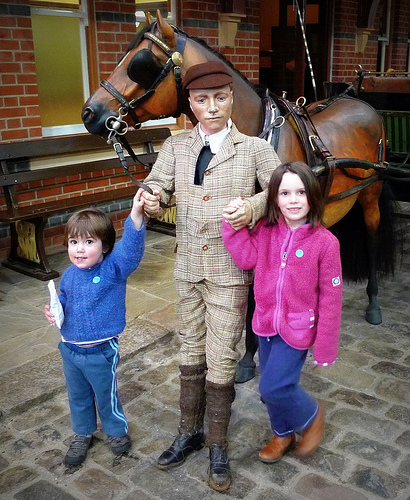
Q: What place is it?
A: It is a street.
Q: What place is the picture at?
A: It is at the street.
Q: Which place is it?
A: It is a street.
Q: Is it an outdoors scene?
A: Yes, it is outdoors.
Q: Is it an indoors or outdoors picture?
A: It is outdoors.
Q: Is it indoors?
A: No, it is outdoors.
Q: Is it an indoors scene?
A: No, it is outdoors.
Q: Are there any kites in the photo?
A: No, there are no kites.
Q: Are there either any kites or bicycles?
A: No, there are no kites or bicycles.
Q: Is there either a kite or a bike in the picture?
A: No, there are no kites or bikes.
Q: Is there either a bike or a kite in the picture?
A: No, there are no kites or bikes.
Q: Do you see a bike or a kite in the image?
A: No, there are no kites or bikes.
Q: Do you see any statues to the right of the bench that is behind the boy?
A: Yes, there is a statue to the right of the bench.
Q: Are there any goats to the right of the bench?
A: No, there is a statue to the right of the bench.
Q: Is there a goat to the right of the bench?
A: No, there is a statue to the right of the bench.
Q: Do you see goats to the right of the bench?
A: No, there is a statue to the right of the bench.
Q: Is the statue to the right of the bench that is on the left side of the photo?
A: Yes, the statue is to the right of the bench.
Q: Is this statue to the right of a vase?
A: No, the statue is to the right of the bench.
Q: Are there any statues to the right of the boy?
A: Yes, there is a statue to the right of the boy.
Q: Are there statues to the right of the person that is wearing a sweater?
A: Yes, there is a statue to the right of the boy.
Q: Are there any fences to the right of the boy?
A: No, there is a statue to the right of the boy.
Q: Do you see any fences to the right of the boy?
A: No, there is a statue to the right of the boy.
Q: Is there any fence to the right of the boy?
A: No, there is a statue to the right of the boy.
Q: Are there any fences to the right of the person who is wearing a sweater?
A: No, there is a statue to the right of the boy.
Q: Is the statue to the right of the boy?
A: Yes, the statue is to the right of the boy.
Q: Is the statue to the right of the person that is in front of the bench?
A: Yes, the statue is to the right of the boy.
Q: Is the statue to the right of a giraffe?
A: No, the statue is to the right of the boy.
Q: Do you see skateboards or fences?
A: No, there are no fences or skateboards.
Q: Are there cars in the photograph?
A: No, there are no cars.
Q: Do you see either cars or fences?
A: No, there are no cars or fences.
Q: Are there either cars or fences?
A: No, there are no cars or fences.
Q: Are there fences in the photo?
A: No, there are no fences.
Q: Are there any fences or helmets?
A: No, there are no fences or helmets.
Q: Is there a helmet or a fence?
A: No, there are no fences or helmets.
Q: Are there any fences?
A: No, there are no fences.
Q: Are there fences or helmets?
A: No, there are no fences or helmets.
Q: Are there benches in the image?
A: Yes, there is a bench.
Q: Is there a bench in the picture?
A: Yes, there is a bench.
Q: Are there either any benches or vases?
A: Yes, there is a bench.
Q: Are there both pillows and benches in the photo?
A: No, there is a bench but no pillows.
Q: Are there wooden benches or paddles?
A: Yes, there is a wood bench.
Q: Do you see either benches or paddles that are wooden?
A: Yes, the bench is wooden.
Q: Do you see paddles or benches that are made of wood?
A: Yes, the bench is made of wood.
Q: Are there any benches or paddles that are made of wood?
A: Yes, the bench is made of wood.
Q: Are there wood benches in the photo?
A: Yes, there is a wood bench.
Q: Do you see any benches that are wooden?
A: Yes, there is a wood bench.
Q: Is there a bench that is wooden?
A: Yes, there is a bench that is wooden.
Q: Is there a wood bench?
A: Yes, there is a bench that is made of wood.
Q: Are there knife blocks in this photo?
A: No, there are no knife blocks.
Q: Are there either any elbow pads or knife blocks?
A: No, there are no knife blocks or elbow pads.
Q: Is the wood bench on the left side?
A: Yes, the bench is on the left of the image.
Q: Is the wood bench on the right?
A: No, the bench is on the left of the image.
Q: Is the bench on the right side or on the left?
A: The bench is on the left of the image.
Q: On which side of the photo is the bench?
A: The bench is on the left of the image.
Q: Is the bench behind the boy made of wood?
A: Yes, the bench is made of wood.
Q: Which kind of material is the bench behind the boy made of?
A: The bench is made of wood.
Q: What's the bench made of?
A: The bench is made of wood.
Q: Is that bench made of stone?
A: No, the bench is made of wood.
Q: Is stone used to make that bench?
A: No, the bench is made of wood.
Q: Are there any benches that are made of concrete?
A: No, there is a bench but it is made of wood.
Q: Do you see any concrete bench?
A: No, there is a bench but it is made of wood.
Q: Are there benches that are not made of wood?
A: No, there is a bench but it is made of wood.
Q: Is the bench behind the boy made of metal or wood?
A: The bench is made of wood.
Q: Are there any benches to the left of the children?
A: Yes, there is a bench to the left of the children.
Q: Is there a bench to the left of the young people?
A: Yes, there is a bench to the left of the children.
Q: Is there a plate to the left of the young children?
A: No, there is a bench to the left of the children.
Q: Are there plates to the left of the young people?
A: No, there is a bench to the left of the children.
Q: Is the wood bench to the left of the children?
A: Yes, the bench is to the left of the children.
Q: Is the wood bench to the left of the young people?
A: Yes, the bench is to the left of the children.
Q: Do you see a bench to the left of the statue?
A: Yes, there is a bench to the left of the statue.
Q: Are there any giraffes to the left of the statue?
A: No, there is a bench to the left of the statue.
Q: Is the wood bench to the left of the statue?
A: Yes, the bench is to the left of the statue.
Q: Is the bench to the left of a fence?
A: No, the bench is to the left of the statue.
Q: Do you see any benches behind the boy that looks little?
A: Yes, there is a bench behind the boy.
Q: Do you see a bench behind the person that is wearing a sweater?
A: Yes, there is a bench behind the boy.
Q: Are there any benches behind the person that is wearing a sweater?
A: Yes, there is a bench behind the boy.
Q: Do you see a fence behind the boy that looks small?
A: No, there is a bench behind the boy.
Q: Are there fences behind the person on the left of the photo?
A: No, there is a bench behind the boy.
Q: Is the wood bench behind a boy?
A: Yes, the bench is behind a boy.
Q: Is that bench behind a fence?
A: No, the bench is behind a boy.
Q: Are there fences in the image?
A: No, there are no fences.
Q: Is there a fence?
A: No, there are no fences.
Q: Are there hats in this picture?
A: Yes, there is a hat.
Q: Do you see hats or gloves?
A: Yes, there is a hat.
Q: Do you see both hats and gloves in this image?
A: No, there is a hat but no gloves.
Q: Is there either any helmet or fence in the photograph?
A: No, there are no fences or helmets.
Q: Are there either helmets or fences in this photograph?
A: No, there are no fences or helmets.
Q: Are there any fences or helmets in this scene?
A: No, there are no fences or helmets.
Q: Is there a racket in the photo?
A: No, there are no rackets.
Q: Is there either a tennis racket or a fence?
A: No, there are no rackets or fences.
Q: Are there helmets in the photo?
A: No, there are no helmets.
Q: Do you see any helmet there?
A: No, there are no helmets.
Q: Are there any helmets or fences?
A: No, there are no helmets or fences.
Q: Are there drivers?
A: No, there are no drivers.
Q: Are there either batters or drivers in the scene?
A: No, there are no drivers or batters.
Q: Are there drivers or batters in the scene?
A: No, there are no drivers or batters.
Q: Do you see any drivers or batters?
A: No, there are no drivers or batters.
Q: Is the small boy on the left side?
A: Yes, the boy is on the left of the image.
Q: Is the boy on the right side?
A: No, the boy is on the left of the image.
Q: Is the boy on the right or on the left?
A: The boy is on the left of the image.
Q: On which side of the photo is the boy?
A: The boy is on the left of the image.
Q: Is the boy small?
A: Yes, the boy is small.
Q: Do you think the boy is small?
A: Yes, the boy is small.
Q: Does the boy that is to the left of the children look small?
A: Yes, the boy is small.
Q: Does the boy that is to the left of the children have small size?
A: Yes, the boy is small.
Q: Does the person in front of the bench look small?
A: Yes, the boy is small.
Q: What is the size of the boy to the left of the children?
A: The boy is small.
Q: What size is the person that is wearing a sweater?
A: The boy is small.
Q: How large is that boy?
A: The boy is small.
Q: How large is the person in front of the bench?
A: The boy is small.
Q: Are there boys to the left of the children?
A: Yes, there is a boy to the left of the children.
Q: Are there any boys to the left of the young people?
A: Yes, there is a boy to the left of the children.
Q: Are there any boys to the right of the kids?
A: No, the boy is to the left of the kids.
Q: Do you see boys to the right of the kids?
A: No, the boy is to the left of the kids.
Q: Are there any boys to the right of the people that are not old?
A: No, the boy is to the left of the kids.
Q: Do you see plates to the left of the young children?
A: No, there is a boy to the left of the children.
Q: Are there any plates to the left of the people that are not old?
A: No, there is a boy to the left of the children.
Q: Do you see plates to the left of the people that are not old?
A: No, there is a boy to the left of the children.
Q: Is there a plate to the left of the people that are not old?
A: No, there is a boy to the left of the children.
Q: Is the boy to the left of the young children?
A: Yes, the boy is to the left of the children.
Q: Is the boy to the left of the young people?
A: Yes, the boy is to the left of the children.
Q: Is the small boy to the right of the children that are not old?
A: No, the boy is to the left of the kids.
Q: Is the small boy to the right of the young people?
A: No, the boy is to the left of the kids.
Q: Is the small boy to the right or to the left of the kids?
A: The boy is to the left of the kids.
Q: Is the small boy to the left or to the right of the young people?
A: The boy is to the left of the kids.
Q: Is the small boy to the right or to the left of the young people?
A: The boy is to the left of the kids.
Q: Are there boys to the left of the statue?
A: Yes, there is a boy to the left of the statue.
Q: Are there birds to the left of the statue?
A: No, there is a boy to the left of the statue.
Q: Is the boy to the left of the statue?
A: Yes, the boy is to the left of the statue.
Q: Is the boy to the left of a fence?
A: No, the boy is to the left of the statue.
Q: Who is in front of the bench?
A: The boy is in front of the bench.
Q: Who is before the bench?
A: The boy is in front of the bench.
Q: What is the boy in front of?
A: The boy is in front of the bench.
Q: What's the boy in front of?
A: The boy is in front of the bench.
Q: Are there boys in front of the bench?
A: Yes, there is a boy in front of the bench.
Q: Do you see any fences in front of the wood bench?
A: No, there is a boy in front of the bench.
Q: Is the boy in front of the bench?
A: Yes, the boy is in front of the bench.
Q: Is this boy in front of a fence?
A: No, the boy is in front of the bench.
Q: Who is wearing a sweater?
A: The boy is wearing a sweater.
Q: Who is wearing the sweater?
A: The boy is wearing a sweater.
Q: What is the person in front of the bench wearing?
A: The boy is wearing a sweater.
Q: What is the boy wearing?
A: The boy is wearing a sweater.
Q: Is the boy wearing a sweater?
A: Yes, the boy is wearing a sweater.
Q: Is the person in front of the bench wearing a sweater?
A: Yes, the boy is wearing a sweater.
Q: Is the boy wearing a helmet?
A: No, the boy is wearing a sweater.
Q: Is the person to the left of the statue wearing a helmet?
A: No, the boy is wearing a sweater.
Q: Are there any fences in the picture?
A: No, there are no fences.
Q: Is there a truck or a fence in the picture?
A: No, there are no fences or trucks.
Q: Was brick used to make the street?
A: Yes, the street is made of brick.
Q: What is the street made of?
A: The street is made of brick.